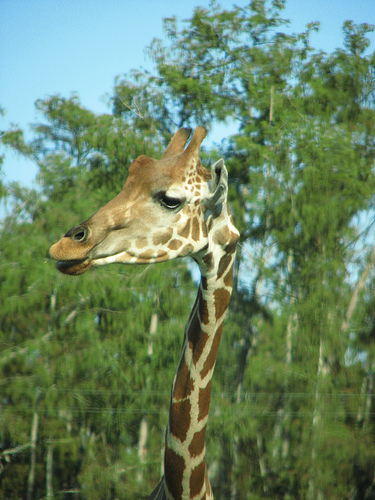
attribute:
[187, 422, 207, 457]
spot — brown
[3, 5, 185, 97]
clouds — white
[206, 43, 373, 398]
tree — brown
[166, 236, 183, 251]
spot — brown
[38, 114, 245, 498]
giraffe — looking down, brown, tan, pictured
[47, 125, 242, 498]
giraffe pattern — square, rectangular, oblong, brown, tan, unique, colorful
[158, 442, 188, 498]
spot — brown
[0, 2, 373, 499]
leaves — green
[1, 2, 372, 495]
tree — brown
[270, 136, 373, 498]
tree — foliage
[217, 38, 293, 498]
tree — foliage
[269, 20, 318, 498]
tree — foliage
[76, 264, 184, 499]
tree — foliage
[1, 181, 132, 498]
tree — foliage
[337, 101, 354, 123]
leaf — green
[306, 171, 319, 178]
leaf — green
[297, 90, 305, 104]
leaf — green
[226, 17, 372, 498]
tree — brown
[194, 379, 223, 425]
spot — brown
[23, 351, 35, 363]
leaf — green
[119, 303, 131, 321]
leaf — green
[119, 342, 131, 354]
leaf — green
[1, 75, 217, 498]
tree — brown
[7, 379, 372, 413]
fence — wire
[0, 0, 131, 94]
sky — clear, blue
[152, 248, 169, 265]
spot — brown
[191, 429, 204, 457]
spot — brown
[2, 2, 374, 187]
sky — blue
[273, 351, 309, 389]
leaves — green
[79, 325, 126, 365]
leaves — green